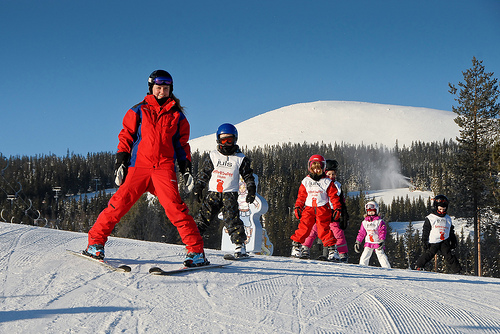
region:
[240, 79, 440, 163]
A snow covered mountain in the background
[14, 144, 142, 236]
Trees all around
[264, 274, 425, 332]
Tracks marking up the snow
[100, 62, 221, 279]
An adult skier in a red outfit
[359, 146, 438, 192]
Spraying snow on the hillside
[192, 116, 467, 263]
Five skiing children on a slope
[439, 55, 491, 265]
A tall tree close by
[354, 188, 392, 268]
A girl in a pink coat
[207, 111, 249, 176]
A boy with a blue helmet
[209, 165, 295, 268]
Models of children skiing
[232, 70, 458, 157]
Snow covered mountain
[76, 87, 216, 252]
Red and purple ski suit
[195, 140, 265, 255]
Black and white ski suite with advertisement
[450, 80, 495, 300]
Pine tree on hill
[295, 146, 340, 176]
Red ski helment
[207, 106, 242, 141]
Blue and yellow ski helment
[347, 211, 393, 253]
Pink and white ski jacket with advertisement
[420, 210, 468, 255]
Black and white ski jacket with advertisement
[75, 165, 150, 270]
Right leg of skier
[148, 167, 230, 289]
Left leg of skier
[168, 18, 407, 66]
this is the sky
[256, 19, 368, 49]
the sky is blue in color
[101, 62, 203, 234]
this is a boy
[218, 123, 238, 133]
this is a helmet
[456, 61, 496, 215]
this is a tree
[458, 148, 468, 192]
the tree has green leaves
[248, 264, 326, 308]
this is the sand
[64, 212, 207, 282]
the legs are part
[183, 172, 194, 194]
this is a glove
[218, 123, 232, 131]
the helmet is blue in color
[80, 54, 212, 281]
female skier wearing red and blue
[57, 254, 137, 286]
ski on the snow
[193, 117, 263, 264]
young skier wearing black and white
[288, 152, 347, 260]
two young skiers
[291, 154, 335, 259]
young female skier wearing red and white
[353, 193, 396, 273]
young female skier wearing pink and white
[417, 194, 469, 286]
skier wearing black and white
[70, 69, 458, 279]
group of young skiers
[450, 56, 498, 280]
very tall tree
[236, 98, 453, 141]
snow covered mountain top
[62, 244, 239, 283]
A pair of skiis.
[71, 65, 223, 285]
An adult skier.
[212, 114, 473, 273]
children skiing.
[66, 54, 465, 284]
A group of people skiing.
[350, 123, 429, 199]
Snow spray in the background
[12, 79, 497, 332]
A snowy mountains.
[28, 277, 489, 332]
Ski tracks in the snow.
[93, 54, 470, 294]
Skiers posing for a photo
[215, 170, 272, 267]
A large cutout snowman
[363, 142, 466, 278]
Two children behind the others